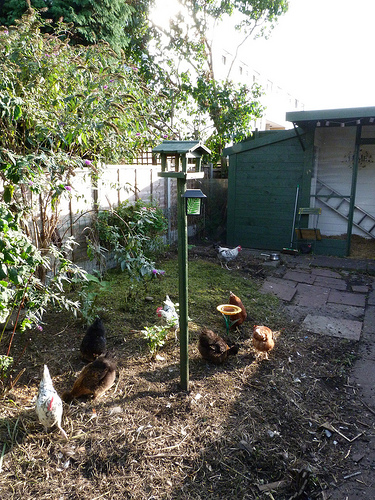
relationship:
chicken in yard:
[250, 320, 279, 353] [17, 210, 370, 496]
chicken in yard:
[34, 368, 64, 415] [17, 210, 370, 496]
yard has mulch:
[17, 210, 370, 496] [26, 399, 326, 499]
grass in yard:
[134, 255, 287, 331] [17, 210, 370, 496]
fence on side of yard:
[3, 161, 202, 239] [17, 210, 370, 496]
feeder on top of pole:
[152, 133, 205, 182] [176, 180, 193, 395]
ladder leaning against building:
[310, 178, 374, 236] [222, 108, 373, 256]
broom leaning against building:
[279, 180, 303, 260] [222, 108, 373, 256]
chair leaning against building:
[294, 205, 326, 254] [222, 108, 373, 256]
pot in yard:
[217, 299, 243, 330] [17, 210, 370, 496]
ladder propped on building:
[310, 178, 374, 236] [222, 108, 373, 256]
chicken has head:
[214, 238, 244, 271] [237, 243, 245, 253]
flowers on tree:
[147, 264, 174, 285] [1, 21, 171, 376]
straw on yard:
[197, 418, 284, 467] [17, 210, 370, 496]